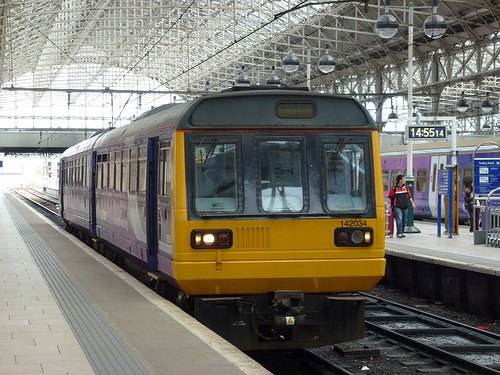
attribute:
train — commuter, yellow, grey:
[57, 86, 387, 352]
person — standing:
[388, 174, 416, 237]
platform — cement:
[386, 214, 499, 325]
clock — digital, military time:
[404, 114, 460, 238]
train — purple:
[381, 145, 499, 224]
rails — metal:
[1, 0, 500, 132]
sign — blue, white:
[472, 160, 499, 196]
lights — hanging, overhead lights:
[375, 13, 447, 42]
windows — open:
[95, 153, 110, 163]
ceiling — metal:
[1, 2, 499, 137]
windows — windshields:
[193, 134, 367, 217]